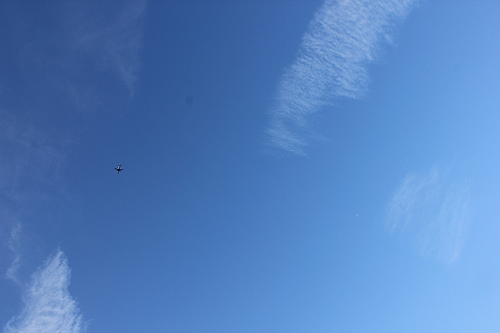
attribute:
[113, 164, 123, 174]
plane — flying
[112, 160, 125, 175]
plane — black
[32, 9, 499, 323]
sky — clear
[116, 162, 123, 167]
wing — tail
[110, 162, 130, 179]
plane — black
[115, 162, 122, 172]
aircraft — flying high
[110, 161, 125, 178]
aircraft — flying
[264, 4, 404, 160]
cloud — white, diffuse, thin, long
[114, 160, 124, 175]
aircraft — blue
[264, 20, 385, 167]
white cloud — large , white 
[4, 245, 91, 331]
cloud — thin , white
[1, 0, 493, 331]
sky — blue, tones of blue, clear , cloudless , bright 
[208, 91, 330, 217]
sky — blue 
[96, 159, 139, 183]
plane — black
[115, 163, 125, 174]
plane — black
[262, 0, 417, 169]
cloud — white 